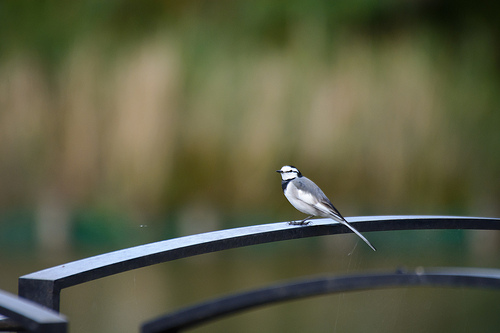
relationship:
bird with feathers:
[276, 165, 378, 252] [296, 185, 311, 205]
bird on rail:
[276, 165, 378, 252] [35, 198, 272, 321]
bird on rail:
[276, 165, 378, 252] [40, 220, 267, 293]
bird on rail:
[276, 165, 378, 252] [42, 221, 274, 322]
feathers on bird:
[295, 184, 320, 208] [276, 165, 378, 252]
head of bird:
[275, 157, 305, 183] [276, 165, 378, 252]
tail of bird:
[325, 205, 384, 255] [276, 165, 378, 252]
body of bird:
[282, 176, 330, 215] [276, 165, 378, 252]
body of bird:
[279, 176, 339, 213] [276, 165, 378, 252]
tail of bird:
[329, 207, 378, 251] [276, 165, 378, 252]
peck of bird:
[264, 157, 284, 180] [259, 140, 388, 263]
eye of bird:
[282, 160, 294, 180] [248, 153, 391, 263]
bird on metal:
[276, 165, 378, 252] [8, 202, 497, 331]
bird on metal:
[259, 140, 388, 263] [8, 202, 497, 331]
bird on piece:
[276, 165, 378, 252] [0, 199, 480, 315]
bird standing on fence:
[276, 165, 378, 252] [2, 208, 489, 331]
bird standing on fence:
[259, 140, 388, 263] [2, 208, 489, 331]